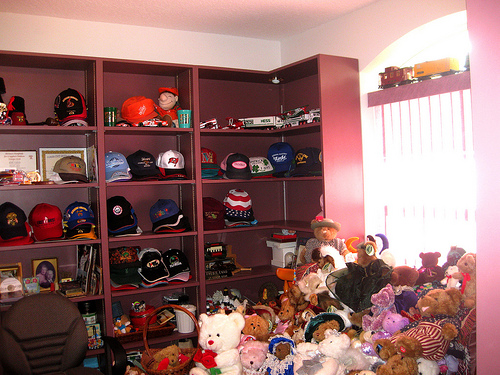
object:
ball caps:
[101, 82, 203, 337]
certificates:
[0, 149, 38, 184]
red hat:
[27, 201, 64, 242]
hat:
[223, 152, 253, 179]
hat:
[203, 191, 225, 233]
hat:
[269, 141, 293, 171]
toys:
[202, 106, 324, 128]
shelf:
[197, 117, 327, 138]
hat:
[63, 201, 94, 228]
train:
[377, 51, 469, 85]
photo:
[32, 255, 59, 291]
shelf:
[7, 278, 102, 301]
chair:
[0, 292, 129, 375]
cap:
[0, 200, 28, 241]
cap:
[25, 202, 63, 244]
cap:
[63, 202, 99, 240]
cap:
[0, 221, 34, 246]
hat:
[265, 140, 297, 173]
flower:
[190, 348, 200, 363]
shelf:
[364, 70, 471, 110]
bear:
[407, 285, 464, 360]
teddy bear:
[300, 213, 349, 265]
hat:
[307, 217, 340, 229]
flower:
[313, 211, 327, 222]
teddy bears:
[348, 284, 410, 344]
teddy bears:
[282, 293, 330, 346]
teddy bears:
[239, 315, 269, 360]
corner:
[263, 34, 374, 277]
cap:
[198, 147, 221, 181]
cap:
[216, 152, 251, 179]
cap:
[245, 154, 274, 181]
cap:
[268, 138, 296, 179]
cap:
[290, 148, 323, 178]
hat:
[28, 203, 63, 238]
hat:
[51, 84, 86, 119]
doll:
[299, 320, 347, 332]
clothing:
[411, 315, 454, 357]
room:
[0, 0, 499, 375]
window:
[359, 6, 478, 269]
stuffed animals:
[154, 218, 480, 374]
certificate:
[37, 144, 91, 185]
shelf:
[201, 218, 288, 238]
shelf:
[109, 229, 196, 242]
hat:
[222, 185, 253, 219]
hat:
[247, 154, 276, 178]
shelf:
[109, 271, 199, 296]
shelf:
[0, 179, 98, 192]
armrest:
[92, 335, 128, 373]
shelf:
[106, 121, 194, 133]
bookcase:
[97, 57, 204, 368]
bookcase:
[0, 49, 112, 374]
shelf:
[0, 235, 101, 251]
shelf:
[104, 230, 197, 242]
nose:
[206, 338, 216, 345]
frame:
[32, 256, 59, 290]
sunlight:
[363, 154, 480, 220]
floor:
[126, 358, 463, 369]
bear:
[188, 311, 248, 374]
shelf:
[4, 180, 103, 190]